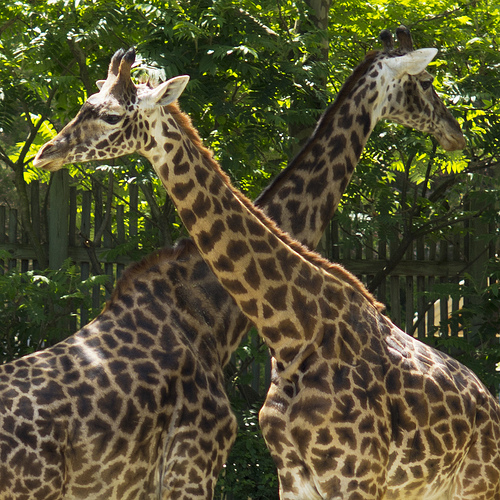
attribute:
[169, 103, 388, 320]
fur — brown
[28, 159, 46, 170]
lip — sticking out, upper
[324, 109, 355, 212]
neck — long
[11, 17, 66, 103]
leaves — green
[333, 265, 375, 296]
hairs — brown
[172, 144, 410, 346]
neck — lower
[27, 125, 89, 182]
nose — giraffe's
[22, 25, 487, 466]
giraffes — side by side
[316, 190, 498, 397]
fence — WOODEN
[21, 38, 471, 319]
giraffes — different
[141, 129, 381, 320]
necks — crisscrossed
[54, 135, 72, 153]
nostril — open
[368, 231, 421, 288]
branch — tree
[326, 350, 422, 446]
lines — white